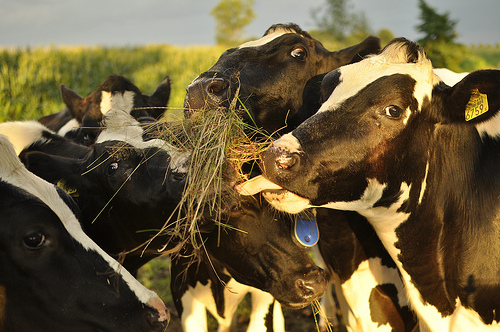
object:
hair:
[367, 37, 426, 65]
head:
[258, 39, 441, 214]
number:
[465, 104, 483, 120]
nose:
[276, 154, 297, 169]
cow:
[194, 173, 329, 309]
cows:
[38, 75, 171, 148]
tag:
[465, 89, 489, 122]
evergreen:
[413, 0, 459, 42]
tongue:
[235, 174, 283, 196]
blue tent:
[6, 12, 324, 329]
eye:
[384, 105, 403, 118]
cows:
[183, 22, 381, 135]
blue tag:
[294, 211, 320, 248]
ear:
[450, 69, 498, 124]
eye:
[24, 229, 45, 247]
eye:
[290, 47, 308, 60]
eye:
[107, 162, 119, 175]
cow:
[0, 134, 169, 332]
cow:
[235, 37, 498, 332]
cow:
[1, 108, 237, 279]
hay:
[73, 73, 290, 293]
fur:
[317, 130, 457, 166]